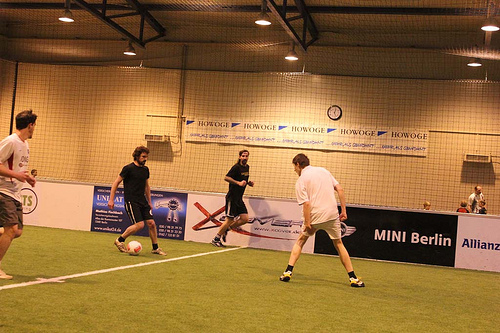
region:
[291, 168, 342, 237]
the shirt is white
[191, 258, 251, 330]
the court is green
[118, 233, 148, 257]
the ball is red and white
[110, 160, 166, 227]
the clothes are black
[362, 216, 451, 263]
the sponsor is mini berlin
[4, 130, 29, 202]
the shirt is white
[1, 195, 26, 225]
the short is brown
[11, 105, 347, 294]
the people are four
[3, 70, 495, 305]
gam being played is soccer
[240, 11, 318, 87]
light is on the roof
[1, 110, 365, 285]
People are playing soccer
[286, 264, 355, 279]
The socks are black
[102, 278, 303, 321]
The field is green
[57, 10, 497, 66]
Lights are hanging down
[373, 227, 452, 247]
The text is white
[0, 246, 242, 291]
White line on field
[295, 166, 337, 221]
The shirt is white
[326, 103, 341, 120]
A clock on the wall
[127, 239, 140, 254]
Ball is white and red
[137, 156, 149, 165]
Man has a beard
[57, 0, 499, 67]
lights suspended from ceiling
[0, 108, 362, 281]
four men playing soccer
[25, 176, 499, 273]
long wall with advertisements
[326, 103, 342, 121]
clock with black frame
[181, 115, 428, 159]
banner with blue triangles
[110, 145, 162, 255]
man with ball at feet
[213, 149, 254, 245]
man in black running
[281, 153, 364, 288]
man in white shirt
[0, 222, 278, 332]
white line on green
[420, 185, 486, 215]
adult and three children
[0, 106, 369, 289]
four men playing indoor soccer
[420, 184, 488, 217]
people standing on other side of net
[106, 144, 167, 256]
man in black kicking the ball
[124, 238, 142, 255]
a white and red soccer ball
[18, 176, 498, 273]
advertisements around edge of wall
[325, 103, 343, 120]
clock on wall above banner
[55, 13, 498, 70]
lights hanging from ceiling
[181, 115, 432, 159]
white and blue banner on wall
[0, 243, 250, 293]
white line across field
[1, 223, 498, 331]
green floor of indoor soccer field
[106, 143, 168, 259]
male soccer player taking the ball upfield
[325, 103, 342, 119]
indoor wall clock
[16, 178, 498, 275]
advertising boards at indoor soccer match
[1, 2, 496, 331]
four soccer players during an indoor soccer match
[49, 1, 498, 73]
overhead suspended lighting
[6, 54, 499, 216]
protective net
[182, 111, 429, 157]
advertising banner on wall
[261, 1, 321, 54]
ceiling joist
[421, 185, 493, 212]
people at the indoor soccer match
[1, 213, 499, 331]
indoor artificial turf